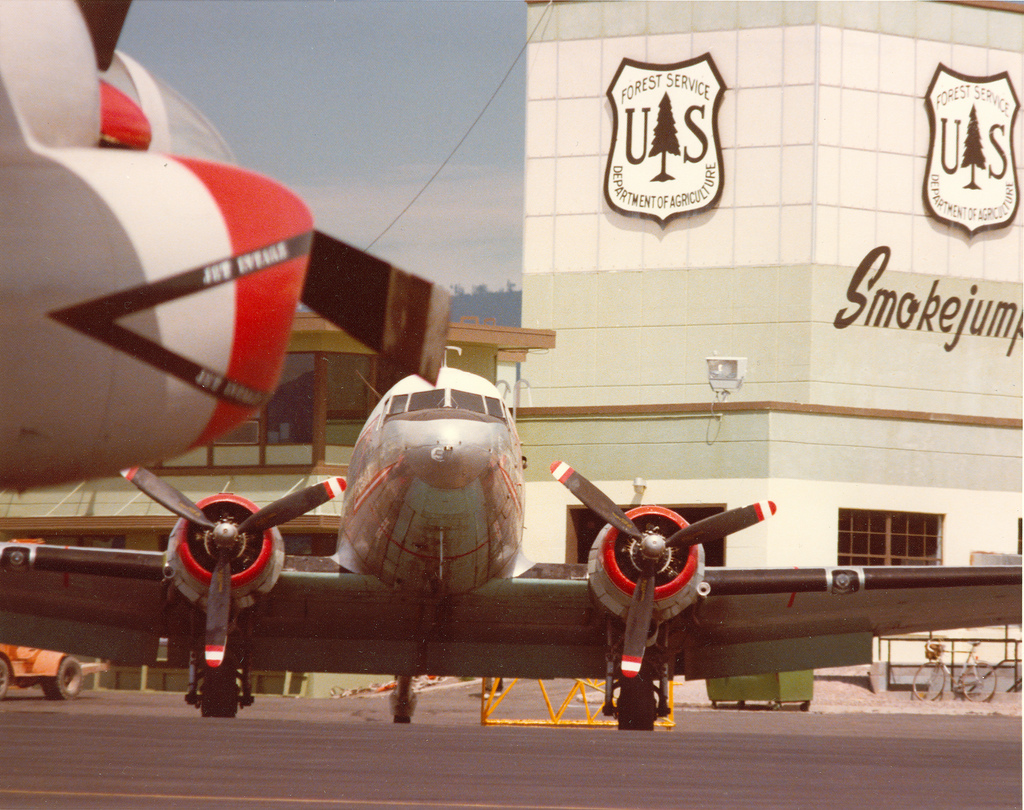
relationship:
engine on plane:
[546, 452, 782, 694] [0, 322, 1024, 739]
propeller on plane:
[553, 456, 783, 690] [0, 322, 1024, 739]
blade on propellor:
[197, 554, 234, 680] [121, 452, 349, 675]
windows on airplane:
[374, 383, 513, 427] [7, 331, 988, 740]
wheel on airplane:
[177, 662, 258, 729] [7, 331, 988, 740]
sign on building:
[586, 48, 729, 234] [516, 5, 992, 716]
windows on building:
[827, 508, 953, 571] [516, 5, 992, 716]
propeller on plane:
[195, 545, 230, 670] [0, 322, 1024, 739]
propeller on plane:
[618, 580, 670, 682] [0, 322, 1024, 739]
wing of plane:
[512, 564, 984, 683] [0, 322, 1024, 739]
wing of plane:
[2, 532, 352, 684] [0, 322, 1024, 739]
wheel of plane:
[176, 662, 256, 728] [0, 322, 1024, 739]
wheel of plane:
[598, 667, 674, 733] [0, 346, 981, 750]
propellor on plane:
[121, 452, 350, 675] [0, 346, 981, 750]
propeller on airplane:
[102, 444, 237, 550] [0, 346, 1024, 739]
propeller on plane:
[175, 579, 249, 679] [0, 322, 1024, 739]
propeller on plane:
[540, 459, 662, 559] [0, 322, 1024, 739]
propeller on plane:
[668, 497, 779, 545] [0, 322, 1024, 739]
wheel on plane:
[176, 662, 256, 728] [0, 322, 1024, 739]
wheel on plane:
[590, 694, 673, 746] [0, 322, 1024, 739]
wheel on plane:
[33, 655, 111, 701] [4, 493, 162, 727]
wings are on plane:
[0, 512, 1022, 688] [0, 322, 1024, 739]